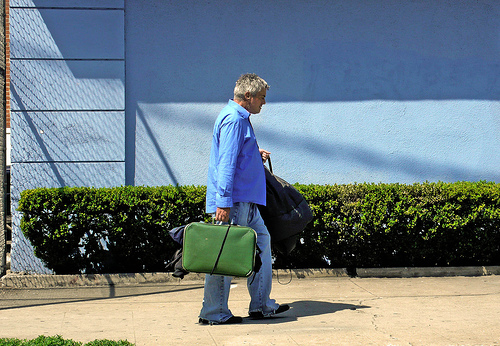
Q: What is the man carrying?
A: Bags.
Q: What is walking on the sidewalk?
A: The man.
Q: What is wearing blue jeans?
A: The man.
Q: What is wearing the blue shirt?
A: The man.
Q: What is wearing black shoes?
A: The man.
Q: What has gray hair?
A: The man.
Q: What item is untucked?
A: The man's shirt.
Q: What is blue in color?
A: The concrete wall.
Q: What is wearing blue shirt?
A: The man.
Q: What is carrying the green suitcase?
A: The man in the blue shirt.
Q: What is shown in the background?
A: A blue wall.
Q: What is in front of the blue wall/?
A: Bushes.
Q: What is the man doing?
A: Walking with a bag.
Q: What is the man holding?
A: A green suitcase.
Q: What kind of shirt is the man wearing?
A: Blue denim long sleeved shirt.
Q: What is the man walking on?
A: Concrete.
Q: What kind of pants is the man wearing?
A: Blue jeans.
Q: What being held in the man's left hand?
A: A large bag.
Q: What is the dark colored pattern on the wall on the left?
A: A shadow of a fence.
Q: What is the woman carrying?
A: A bag.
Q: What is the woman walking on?
A: Sidewalk.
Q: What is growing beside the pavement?
A: Bushes.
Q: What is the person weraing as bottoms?
A: Pants.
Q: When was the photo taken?
A: Daytime.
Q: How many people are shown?
A: One.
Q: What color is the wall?
A: Blue.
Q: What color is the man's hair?
A: Gray.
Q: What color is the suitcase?
A: Green.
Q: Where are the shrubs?
A: In front of the building.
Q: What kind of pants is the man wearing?
A: Jeans.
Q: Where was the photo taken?
A: Beside blue building.